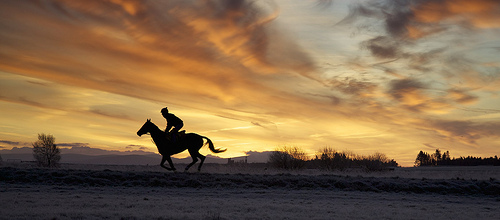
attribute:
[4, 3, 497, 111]
sky — beautiful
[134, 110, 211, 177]
horse — back 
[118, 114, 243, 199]
horse — back 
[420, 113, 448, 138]
ground — sunset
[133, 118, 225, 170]
horse — running, standing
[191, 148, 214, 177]
back legs — back 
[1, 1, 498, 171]
sky — orange, beautiful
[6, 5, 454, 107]
sky — during 